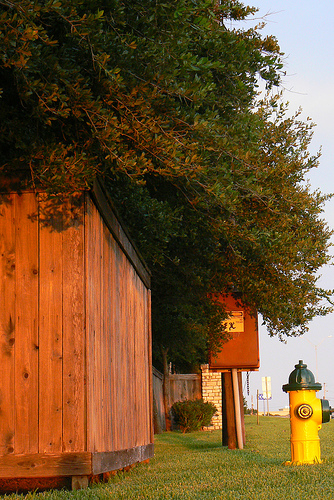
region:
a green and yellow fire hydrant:
[279, 359, 332, 468]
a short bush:
[169, 394, 217, 437]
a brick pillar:
[201, 361, 224, 430]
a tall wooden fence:
[0, 169, 158, 486]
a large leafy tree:
[2, 0, 331, 341]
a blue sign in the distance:
[256, 392, 273, 401]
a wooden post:
[221, 365, 250, 450]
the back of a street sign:
[260, 373, 274, 416]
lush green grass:
[9, 412, 332, 498]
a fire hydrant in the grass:
[280, 354, 332, 467]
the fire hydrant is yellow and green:
[281, 361, 333, 465]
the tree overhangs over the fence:
[1, 6, 329, 336]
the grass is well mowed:
[4, 410, 332, 498]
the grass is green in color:
[6, 405, 332, 497]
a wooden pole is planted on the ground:
[212, 291, 253, 447]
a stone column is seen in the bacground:
[199, 363, 228, 433]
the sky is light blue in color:
[239, 0, 332, 413]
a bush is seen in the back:
[168, 399, 213, 433]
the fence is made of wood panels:
[4, 216, 200, 482]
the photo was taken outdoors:
[1, 0, 333, 497]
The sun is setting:
[38, 156, 329, 444]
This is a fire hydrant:
[276, 335, 328, 491]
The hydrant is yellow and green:
[281, 351, 333, 485]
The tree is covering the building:
[77, 95, 270, 363]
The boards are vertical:
[1, 227, 142, 383]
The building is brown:
[17, 231, 154, 420]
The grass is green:
[177, 440, 254, 488]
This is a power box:
[186, 274, 278, 445]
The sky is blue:
[266, 285, 328, 359]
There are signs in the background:
[261, 362, 282, 435]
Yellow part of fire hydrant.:
[289, 389, 322, 466]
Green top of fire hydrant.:
[285, 360, 323, 391]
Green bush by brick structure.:
[159, 398, 217, 436]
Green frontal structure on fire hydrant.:
[319, 397, 330, 422]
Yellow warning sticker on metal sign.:
[214, 306, 246, 334]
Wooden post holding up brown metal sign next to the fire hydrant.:
[222, 370, 249, 449]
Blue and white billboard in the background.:
[255, 388, 272, 401]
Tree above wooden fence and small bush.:
[150, 308, 231, 366]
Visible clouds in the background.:
[244, 0, 333, 419]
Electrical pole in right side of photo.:
[322, 381, 327, 406]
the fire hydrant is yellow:
[283, 357, 333, 465]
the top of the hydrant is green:
[282, 355, 331, 467]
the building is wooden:
[0, 174, 156, 492]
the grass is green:
[4, 412, 333, 498]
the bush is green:
[166, 394, 217, 438]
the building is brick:
[202, 362, 224, 432]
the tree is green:
[0, 0, 333, 374]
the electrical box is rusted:
[207, 274, 259, 374]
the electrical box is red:
[208, 291, 260, 372]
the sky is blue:
[222, 0, 333, 412]